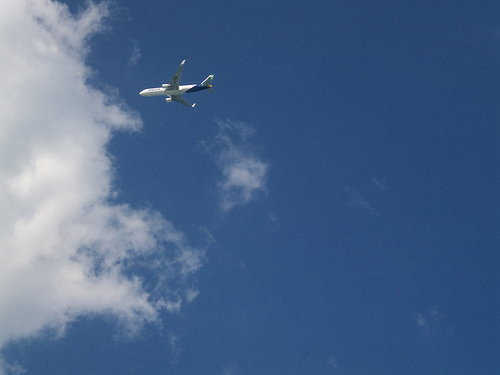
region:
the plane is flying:
[134, 56, 256, 133]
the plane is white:
[125, 51, 248, 135]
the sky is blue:
[310, 26, 405, 154]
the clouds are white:
[1, 30, 133, 228]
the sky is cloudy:
[15, 15, 435, 359]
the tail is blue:
[178, 71, 227, 115]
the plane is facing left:
[121, 43, 238, 123]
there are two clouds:
[52, 69, 307, 328]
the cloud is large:
[18, 17, 143, 359]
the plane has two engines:
[154, 73, 182, 107]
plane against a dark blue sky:
[122, 52, 222, 128]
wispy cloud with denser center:
[201, 120, 311, 220]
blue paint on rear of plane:
[125, 55, 232, 115]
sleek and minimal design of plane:
[130, 55, 220, 120]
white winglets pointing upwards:
[171, 52, 198, 112]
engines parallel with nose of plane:
[132, 75, 177, 102]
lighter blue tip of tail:
[202, 60, 213, 80]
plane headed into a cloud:
[76, 30, 216, 130]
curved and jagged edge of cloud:
[75, 35, 145, 231]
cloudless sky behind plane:
[150, 26, 470, 116]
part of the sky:
[381, 91, 448, 164]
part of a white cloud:
[18, 250, 68, 306]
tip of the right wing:
[187, 99, 201, 114]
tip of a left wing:
[171, 49, 183, 67]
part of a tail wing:
[205, 65, 217, 83]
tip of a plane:
[138, 90, 148, 99]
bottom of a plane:
[152, 89, 182, 99]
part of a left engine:
[159, 80, 170, 90]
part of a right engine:
[161, 91, 173, 103]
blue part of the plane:
[193, 78, 205, 93]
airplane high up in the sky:
[135, 56, 219, 117]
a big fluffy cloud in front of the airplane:
[0, 8, 212, 359]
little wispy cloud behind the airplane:
[199, 104, 301, 247]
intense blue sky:
[5, 0, 498, 371]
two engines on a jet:
[159, 74, 184, 114]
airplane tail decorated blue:
[179, 63, 254, 118]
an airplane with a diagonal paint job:
[134, 44, 230, 129]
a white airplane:
[129, 54, 231, 117]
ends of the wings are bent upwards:
[165, 42, 208, 120]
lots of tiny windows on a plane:
[136, 76, 211, 98]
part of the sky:
[370, 98, 422, 150]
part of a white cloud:
[28, 306, 68, 323]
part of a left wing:
[171, 64, 186, 81]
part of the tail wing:
[202, 70, 216, 81]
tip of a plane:
[136, 86, 151, 101]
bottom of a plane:
[163, 90, 181, 95]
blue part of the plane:
[191, 84, 202, 91]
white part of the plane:
[153, 88, 173, 98]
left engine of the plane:
[163, 82, 176, 89]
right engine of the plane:
[166, 94, 173, 101]